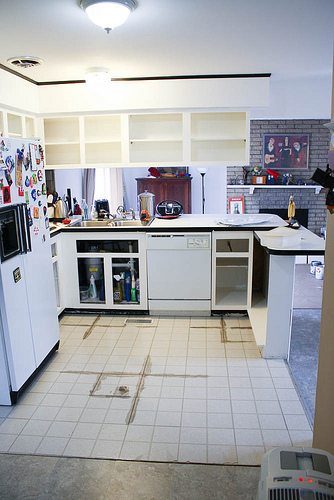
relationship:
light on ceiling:
[78, 1, 136, 32] [1, 4, 331, 77]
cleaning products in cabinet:
[113, 271, 140, 302] [77, 257, 139, 303]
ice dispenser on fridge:
[1, 201, 31, 256] [2, 137, 60, 404]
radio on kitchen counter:
[155, 197, 186, 217] [152, 210, 284, 228]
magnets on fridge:
[0, 137, 48, 241] [2, 137, 60, 404]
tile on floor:
[160, 385, 183, 398] [0, 263, 323, 497]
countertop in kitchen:
[151, 211, 325, 252] [5, 37, 314, 465]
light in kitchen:
[75, 0, 139, 37] [0, 0, 327, 469]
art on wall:
[262, 132, 309, 170] [230, 117, 330, 240]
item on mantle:
[238, 164, 252, 185] [226, 184, 326, 194]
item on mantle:
[251, 166, 268, 185] [226, 184, 326, 194]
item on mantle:
[264, 167, 279, 184] [226, 184, 326, 194]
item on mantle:
[281, 171, 296, 184] [226, 184, 326, 194]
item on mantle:
[295, 177, 308, 187] [226, 184, 326, 194]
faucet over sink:
[99, 209, 115, 219] [68, 219, 112, 228]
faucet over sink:
[99, 209, 115, 219] [108, 220, 152, 227]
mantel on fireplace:
[227, 185, 322, 195] [227, 122, 326, 238]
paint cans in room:
[307, 257, 325, 281] [225, 120, 328, 416]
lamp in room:
[193, 167, 209, 210] [46, 119, 328, 428]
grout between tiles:
[189, 423, 221, 463] [170, 368, 187, 378]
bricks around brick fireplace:
[245, 130, 320, 201] [225, 118, 328, 242]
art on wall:
[262, 132, 309, 170] [250, 120, 324, 131]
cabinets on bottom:
[213, 198, 300, 327] [61, 232, 256, 309]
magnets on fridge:
[40, 181, 48, 195] [2, 137, 60, 404]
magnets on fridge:
[36, 167, 43, 180] [2, 137, 60, 404]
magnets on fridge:
[23, 175, 30, 186] [2, 137, 60, 404]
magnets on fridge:
[30, 188, 38, 201] [2, 137, 60, 404]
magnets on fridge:
[31, 205, 39, 219] [2, 137, 60, 404]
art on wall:
[251, 111, 329, 185] [242, 113, 328, 221]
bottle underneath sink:
[89, 273, 97, 299] [63, 212, 150, 228]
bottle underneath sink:
[130, 275, 134, 301] [63, 212, 150, 228]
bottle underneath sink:
[124, 274, 130, 300] [63, 212, 150, 228]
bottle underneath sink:
[119, 272, 127, 298] [63, 212, 150, 228]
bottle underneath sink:
[112, 275, 123, 302] [63, 212, 150, 228]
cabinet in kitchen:
[4, 108, 252, 171] [0, 0, 327, 469]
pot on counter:
[135, 188, 154, 214] [175, 213, 217, 223]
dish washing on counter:
[283, 193, 296, 220] [147, 208, 287, 244]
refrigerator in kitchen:
[0, 125, 59, 405] [0, 0, 327, 469]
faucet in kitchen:
[95, 206, 118, 219] [40, 89, 327, 485]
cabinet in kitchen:
[68, 248, 158, 310] [0, 0, 327, 469]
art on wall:
[262, 132, 309, 170] [42, 89, 329, 224]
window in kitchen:
[76, 154, 221, 222] [2, 105, 312, 450]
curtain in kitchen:
[50, 162, 170, 214] [5, 37, 314, 465]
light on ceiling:
[75, 0, 137, 36] [0, 0, 329, 83]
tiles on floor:
[61, 313, 266, 451] [81, 329, 216, 414]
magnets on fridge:
[1, 141, 48, 240] [2, 137, 60, 404]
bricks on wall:
[257, 136, 323, 207] [224, 114, 331, 235]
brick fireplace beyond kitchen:
[225, 118, 329, 238] [0, 0, 295, 499]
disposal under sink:
[88, 252, 103, 281] [79, 212, 135, 231]